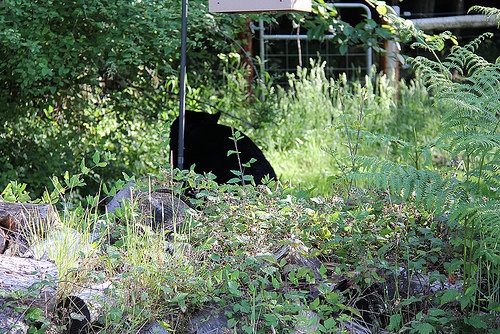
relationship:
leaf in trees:
[0, 0, 236, 218] [140, 65, 162, 88]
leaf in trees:
[0, 0, 236, 218] [4, 4, 281, 163]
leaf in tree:
[0, 0, 236, 218] [138, 63, 163, 90]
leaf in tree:
[104, 96, 114, 105] [138, 63, 163, 90]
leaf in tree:
[116, 110, 128, 117] [138, 63, 163, 90]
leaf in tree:
[0, 0, 236, 218] [2, 0, 411, 203]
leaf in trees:
[0, 0, 236, 218] [64, 36, 276, 297]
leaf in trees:
[0, 0, 236, 218] [3, 7, 498, 164]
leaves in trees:
[273, 1, 425, 52] [3, 7, 498, 164]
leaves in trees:
[176, 172, 424, 332] [3, 7, 498, 164]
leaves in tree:
[173, 205, 372, 317] [383, 38, 397, 91]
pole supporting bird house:
[156, 39, 211, 174] [145, 0, 354, 35]